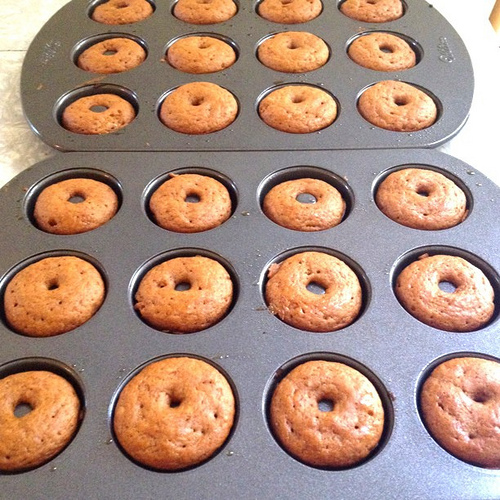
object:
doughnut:
[152, 75, 238, 138]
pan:
[25, 0, 470, 154]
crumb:
[25, 63, 54, 105]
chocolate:
[158, 382, 184, 421]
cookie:
[265, 250, 361, 331]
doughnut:
[257, 81, 340, 133]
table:
[439, 0, 496, 185]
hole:
[385, 94, 418, 112]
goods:
[358, 79, 437, 132]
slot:
[350, 75, 446, 133]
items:
[77, 37, 147, 74]